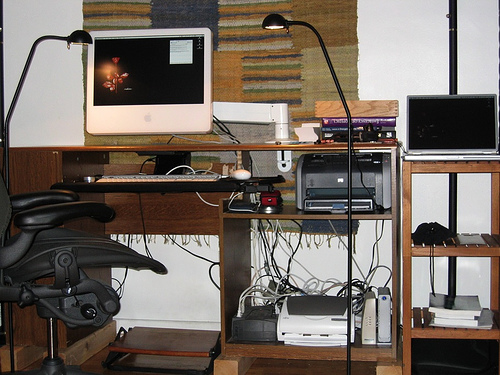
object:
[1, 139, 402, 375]
desk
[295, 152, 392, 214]
fax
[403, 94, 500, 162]
laptop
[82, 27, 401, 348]
electric devices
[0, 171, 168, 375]
chair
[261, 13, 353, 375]
blacklamp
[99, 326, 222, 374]
foot rest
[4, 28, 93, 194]
light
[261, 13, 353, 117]
light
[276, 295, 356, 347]
machine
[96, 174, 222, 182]
keyboard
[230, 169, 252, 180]
computer mouse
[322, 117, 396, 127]
purple book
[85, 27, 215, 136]
monitor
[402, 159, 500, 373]
shelf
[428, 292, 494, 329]
books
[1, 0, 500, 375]
room